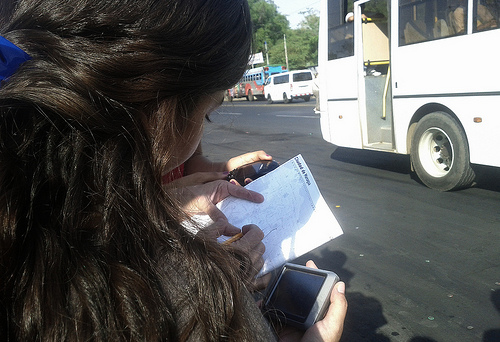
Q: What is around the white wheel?
A: A black tire.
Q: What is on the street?
A: A large bus.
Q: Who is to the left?
A: A woman with dark brown hair.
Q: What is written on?
A: A paper.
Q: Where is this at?
A: A street.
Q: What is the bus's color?
A: White.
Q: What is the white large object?
A: Bus.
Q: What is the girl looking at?
A: An electronic device.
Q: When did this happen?
A: During the day time.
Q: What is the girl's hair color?
A: Brown.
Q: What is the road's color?
A: Black.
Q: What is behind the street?
A: Trees.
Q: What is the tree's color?
A: Green.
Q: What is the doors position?
A: Open.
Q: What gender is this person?
A: Female.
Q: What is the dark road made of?
A: Pavement.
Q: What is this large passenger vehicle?
A: Bus.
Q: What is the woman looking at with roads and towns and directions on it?
A: Map.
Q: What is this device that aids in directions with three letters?
A: GPS.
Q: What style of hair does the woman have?
A: Ponytail.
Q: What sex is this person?
A: Female.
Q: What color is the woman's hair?
A: Dark brown.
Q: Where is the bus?
A: On the street.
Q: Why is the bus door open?
A: To let people in or out.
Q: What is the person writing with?
A: Pencil.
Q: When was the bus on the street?
A: Daytime.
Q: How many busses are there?
A: One.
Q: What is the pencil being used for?
A: Writing.